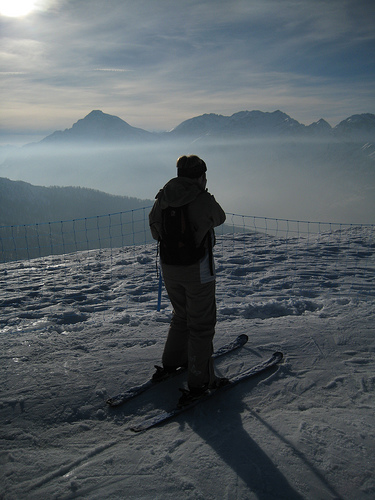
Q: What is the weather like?
A: Blue skies.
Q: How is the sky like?
A: It is cloudy.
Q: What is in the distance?
A: Mountains.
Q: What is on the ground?
A: Snow.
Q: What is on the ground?
A: Snow.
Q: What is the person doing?
A: Skiing.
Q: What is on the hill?
A: Plastic fence.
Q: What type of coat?
A: Snow.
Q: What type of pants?
A: Snow.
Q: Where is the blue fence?
A: In front of the skier.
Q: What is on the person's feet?
A: Two skis.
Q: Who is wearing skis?
A: A man.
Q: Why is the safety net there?
A: To keep skiers safe.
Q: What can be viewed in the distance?
A: A mountain range.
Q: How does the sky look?
A: Blue and sunny.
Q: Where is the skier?
A: On a hill overlooking a mountain range.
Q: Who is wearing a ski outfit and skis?
A: A man.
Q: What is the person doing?
A: Skiing.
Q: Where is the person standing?
A: Ski slope.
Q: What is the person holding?
A: Ski poles.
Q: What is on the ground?
A: Snow.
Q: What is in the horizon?
A: Mountains.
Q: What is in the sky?
A: Clouds.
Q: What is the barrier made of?
A: Black netting.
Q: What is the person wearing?
A: Snow suit.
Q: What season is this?
A: Winter.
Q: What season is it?
A: Winter.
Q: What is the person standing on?
A: Skis.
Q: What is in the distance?
A: Mist.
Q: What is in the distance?
A: Mountains.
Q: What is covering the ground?
A: Snow.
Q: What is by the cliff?
A: Blue net.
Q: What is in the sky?
A: Clouds.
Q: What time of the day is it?
A: Evening.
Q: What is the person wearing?
A: Snowsuit.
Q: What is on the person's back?
A: Book bag.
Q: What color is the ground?
A: White.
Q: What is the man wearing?
A: Hat.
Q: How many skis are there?
A: Two.